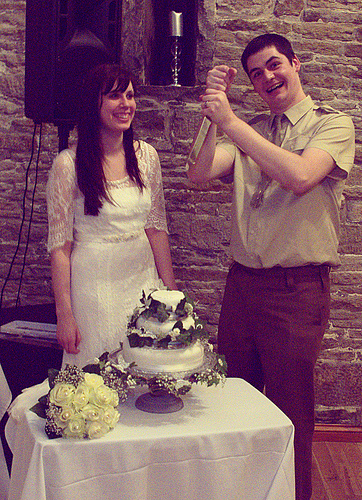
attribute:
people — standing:
[48, 34, 356, 499]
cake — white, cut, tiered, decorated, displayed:
[126, 286, 205, 377]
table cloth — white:
[5, 375, 299, 499]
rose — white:
[48, 373, 123, 441]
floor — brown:
[307, 440, 361, 498]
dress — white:
[48, 139, 168, 374]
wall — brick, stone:
[2, 2, 361, 426]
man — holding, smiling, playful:
[187, 36, 354, 499]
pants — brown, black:
[216, 263, 331, 499]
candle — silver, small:
[168, 34, 187, 86]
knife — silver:
[184, 115, 212, 172]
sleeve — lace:
[46, 152, 74, 253]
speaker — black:
[24, 3, 119, 123]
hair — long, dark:
[74, 65, 146, 217]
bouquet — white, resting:
[41, 366, 118, 436]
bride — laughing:
[45, 65, 176, 376]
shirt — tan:
[229, 96, 357, 269]